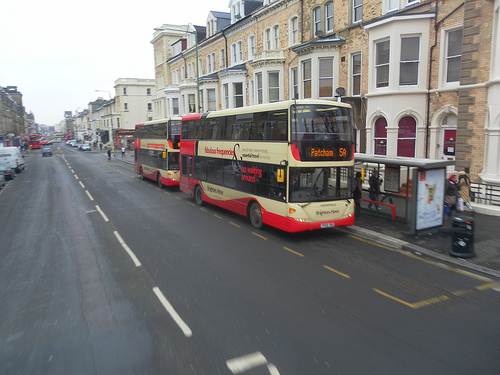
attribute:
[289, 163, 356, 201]
windshield — bus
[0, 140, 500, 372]
street — Black 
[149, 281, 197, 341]
line — white